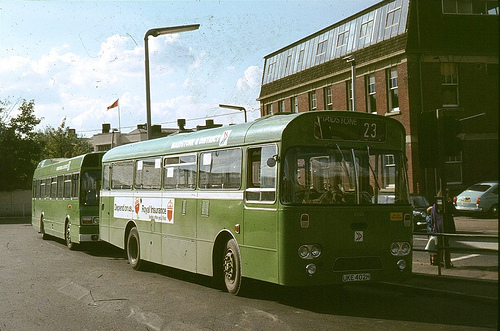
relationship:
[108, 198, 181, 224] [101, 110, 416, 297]
banner on side of bus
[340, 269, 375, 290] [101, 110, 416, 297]
license plate on bus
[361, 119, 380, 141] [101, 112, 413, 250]
number of bus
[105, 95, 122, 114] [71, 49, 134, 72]
flag waving in distance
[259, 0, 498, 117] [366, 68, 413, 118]
building with windows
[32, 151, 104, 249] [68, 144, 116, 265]
bus parked next each other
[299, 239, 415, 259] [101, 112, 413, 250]
headlights on front of bus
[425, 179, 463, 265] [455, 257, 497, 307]
person standing on sidewalk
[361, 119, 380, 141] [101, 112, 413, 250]
number on bus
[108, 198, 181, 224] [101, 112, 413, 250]
sign on bus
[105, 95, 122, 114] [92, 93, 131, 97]
flag flowing in wind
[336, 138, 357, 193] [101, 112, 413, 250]
wipers on bus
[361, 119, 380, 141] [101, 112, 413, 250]
number 23 on front of bus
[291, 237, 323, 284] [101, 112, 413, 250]
lights on front of bus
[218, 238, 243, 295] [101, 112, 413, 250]
wheel on bus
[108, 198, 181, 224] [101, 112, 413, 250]
sign on side of bus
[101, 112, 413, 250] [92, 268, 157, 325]
bus on side of road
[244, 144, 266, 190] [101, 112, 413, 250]
windows on side of bus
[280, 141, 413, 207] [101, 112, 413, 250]
windshield on front of bus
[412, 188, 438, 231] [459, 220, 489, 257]
car parked on side of road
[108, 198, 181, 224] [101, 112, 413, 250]
banner on side of bus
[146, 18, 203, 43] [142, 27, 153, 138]
light mounted to pole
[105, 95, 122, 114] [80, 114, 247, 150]
flag flying over buildings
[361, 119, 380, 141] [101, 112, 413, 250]
number on front of bus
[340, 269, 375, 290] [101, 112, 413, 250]
license plate on bus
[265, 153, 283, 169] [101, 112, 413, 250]
mirror mounted on side of bus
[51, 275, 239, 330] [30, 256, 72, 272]
design in concrete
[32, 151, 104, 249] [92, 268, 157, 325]
bus parked next to road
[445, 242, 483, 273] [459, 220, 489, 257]
line painted on road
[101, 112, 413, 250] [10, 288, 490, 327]
bus parked in a lot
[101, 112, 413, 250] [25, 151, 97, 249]
bus parked behind bus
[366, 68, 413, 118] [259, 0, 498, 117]
windows on top of building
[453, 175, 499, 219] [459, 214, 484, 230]
car parked off street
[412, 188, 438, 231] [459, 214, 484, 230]
black car parked on street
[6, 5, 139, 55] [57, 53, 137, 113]
sky with white clouds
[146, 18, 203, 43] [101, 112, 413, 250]
light above bus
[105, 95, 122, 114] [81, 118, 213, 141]
flag on top of building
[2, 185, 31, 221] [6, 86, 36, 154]
fence in background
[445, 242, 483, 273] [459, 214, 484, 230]
line on street